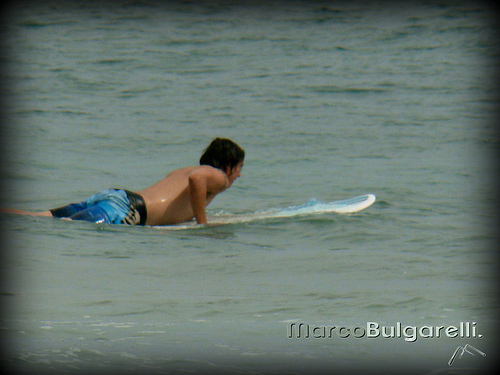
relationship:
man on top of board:
[5, 129, 250, 231] [79, 163, 379, 232]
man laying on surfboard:
[5, 129, 250, 231] [138, 164, 420, 273]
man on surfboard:
[5, 129, 250, 231] [152, 193, 374, 230]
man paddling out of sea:
[5, 129, 250, 231] [1, 5, 489, 368]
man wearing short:
[5, 129, 250, 231] [47, 186, 147, 233]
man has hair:
[5, 129, 250, 231] [198, 134, 241, 168]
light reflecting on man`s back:
[158, 195, 169, 205] [134, 167, 201, 207]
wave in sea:
[266, 68, 497, 106] [1, 5, 489, 368]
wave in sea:
[142, 31, 317, 57] [1, 5, 489, 368]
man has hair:
[5, 129, 250, 231] [198, 132, 245, 170]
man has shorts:
[5, 129, 250, 231] [50, 186, 148, 229]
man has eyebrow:
[5, 129, 250, 231] [237, 159, 251, 169]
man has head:
[5, 129, 250, 231] [199, 134, 242, 182]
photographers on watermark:
[279, 311, 484, 347] [283, 308, 486, 366]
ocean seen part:
[333, 217, 462, 271] [362, 242, 374, 260]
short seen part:
[47, 186, 147, 233] [92, 193, 115, 207]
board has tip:
[79, 163, 406, 253] [353, 182, 395, 224]